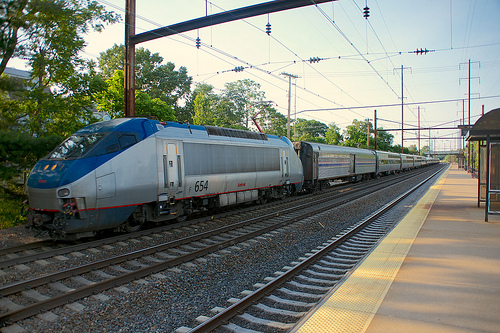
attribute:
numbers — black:
[193, 177, 209, 194]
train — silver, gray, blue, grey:
[20, 110, 442, 241]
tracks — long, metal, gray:
[0, 166, 450, 331]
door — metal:
[152, 132, 188, 192]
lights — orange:
[38, 158, 61, 173]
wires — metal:
[128, 0, 499, 148]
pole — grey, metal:
[275, 67, 303, 138]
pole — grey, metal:
[388, 63, 416, 151]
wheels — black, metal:
[122, 199, 197, 231]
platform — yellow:
[294, 155, 500, 332]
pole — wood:
[357, 116, 377, 149]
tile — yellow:
[294, 159, 452, 331]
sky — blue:
[1, 0, 500, 154]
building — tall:
[0, 65, 50, 151]